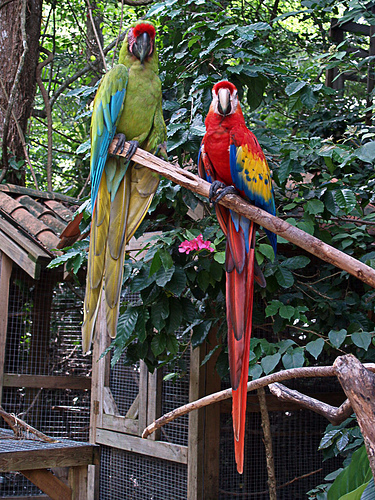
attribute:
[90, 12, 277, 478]
parrots — colored, perched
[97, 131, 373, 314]
stick — enclosed, tan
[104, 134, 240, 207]
claws — black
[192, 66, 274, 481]
bird — red, scarlet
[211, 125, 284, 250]
wings — blue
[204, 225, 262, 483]
tail — long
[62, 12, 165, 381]
parrot — green, blue, military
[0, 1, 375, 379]
trees — green, wild, leafy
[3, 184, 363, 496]
cages — wooden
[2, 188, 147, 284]
roof — tile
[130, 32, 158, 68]
beak — black